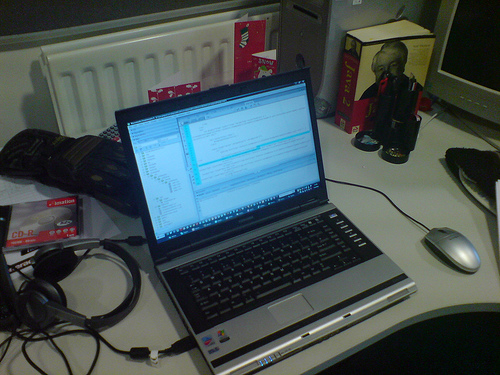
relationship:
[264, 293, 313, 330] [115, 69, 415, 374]
touchpad of laptop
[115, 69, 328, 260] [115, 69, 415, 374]
monitor of laptop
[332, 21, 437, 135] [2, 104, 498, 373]
book on table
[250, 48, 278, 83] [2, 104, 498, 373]
card on table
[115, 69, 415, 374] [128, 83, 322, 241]
laptop with document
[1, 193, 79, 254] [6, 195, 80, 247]
case with red label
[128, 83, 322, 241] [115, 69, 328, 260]
document in word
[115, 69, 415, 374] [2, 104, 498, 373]
laptop on table